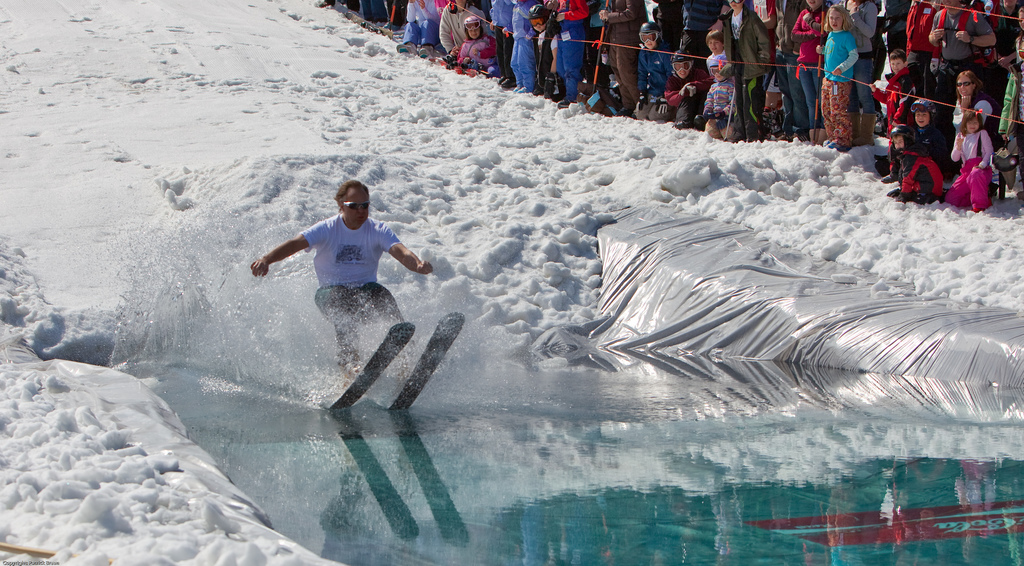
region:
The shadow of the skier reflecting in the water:
[328, 513, 363, 561]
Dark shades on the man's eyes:
[343, 201, 370, 209]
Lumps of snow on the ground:
[670, 159, 775, 195]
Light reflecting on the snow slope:
[8, 18, 88, 246]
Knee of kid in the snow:
[969, 199, 989, 210]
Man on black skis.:
[246, 171, 461, 415]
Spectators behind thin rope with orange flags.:
[553, 13, 1016, 195]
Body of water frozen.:
[301, 402, 1022, 562]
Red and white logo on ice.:
[735, 471, 1011, 554]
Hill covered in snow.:
[2, 0, 1017, 405]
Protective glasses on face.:
[342, 178, 374, 226]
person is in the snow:
[705, 26, 738, 137]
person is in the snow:
[888, 98, 952, 209]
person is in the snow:
[951, 70, 991, 147]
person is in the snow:
[665, 42, 714, 128]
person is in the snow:
[636, 22, 675, 120]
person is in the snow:
[453, 11, 498, 79]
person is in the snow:
[551, 3, 589, 112]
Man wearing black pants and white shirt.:
[246, 177, 428, 358]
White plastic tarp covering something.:
[566, 196, 1019, 399]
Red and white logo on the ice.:
[755, 487, 1021, 552]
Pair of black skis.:
[326, 308, 482, 442]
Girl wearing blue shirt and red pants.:
[811, 0, 868, 146]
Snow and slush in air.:
[142, 163, 575, 410]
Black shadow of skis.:
[313, 378, 494, 533]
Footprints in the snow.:
[48, 35, 369, 118]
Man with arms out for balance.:
[246, 180, 455, 340]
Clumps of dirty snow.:
[673, 133, 828, 220]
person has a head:
[336, 180, 372, 223]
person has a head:
[959, 111, 979, 132]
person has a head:
[909, 98, 929, 128]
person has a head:
[953, 69, 974, 98]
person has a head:
[710, 60, 729, 86]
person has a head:
[667, 53, 693, 76]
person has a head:
[637, 23, 660, 46]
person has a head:
[460, 13, 484, 36]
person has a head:
[526, 4, 543, 27]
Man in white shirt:
[230, 167, 502, 444]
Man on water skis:
[227, 164, 506, 479]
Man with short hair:
[240, 170, 501, 409]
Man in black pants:
[223, 174, 506, 415]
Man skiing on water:
[233, 174, 475, 422]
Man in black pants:
[198, 165, 489, 415]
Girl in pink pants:
[936, 105, 1003, 223]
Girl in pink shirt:
[935, 108, 1000, 207]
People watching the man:
[413, 3, 1009, 203]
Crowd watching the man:
[424, 9, 1016, 206]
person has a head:
[336, 177, 372, 229]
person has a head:
[911, 98, 934, 127]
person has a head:
[958, 70, 977, 99]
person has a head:
[705, 29, 725, 52]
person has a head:
[669, 59, 689, 80]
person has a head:
[642, 29, 659, 52]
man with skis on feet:
[246, 170, 469, 420]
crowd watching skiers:
[329, 0, 1022, 214]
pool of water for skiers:
[54, 337, 1022, 563]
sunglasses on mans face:
[340, 193, 370, 214]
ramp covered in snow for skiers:
[0, 0, 1022, 560]